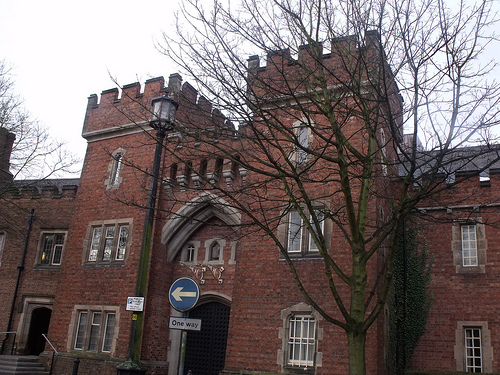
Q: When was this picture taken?
A: Daytime.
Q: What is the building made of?
A: Brick.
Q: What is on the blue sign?
A: White arrow.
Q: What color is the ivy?
A: Green.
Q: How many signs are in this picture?
A: 3.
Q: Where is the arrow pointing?
A: To left.